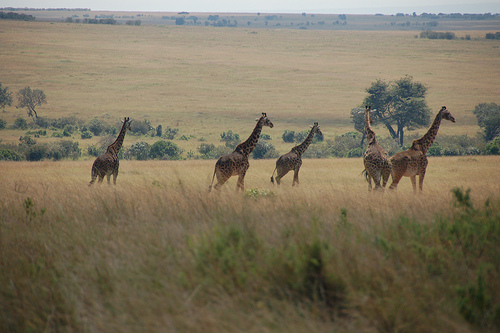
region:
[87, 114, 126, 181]
a tall giraffee wandering the plain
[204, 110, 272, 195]
a tall giraffee wandering the plain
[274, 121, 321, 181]
a tall giraffee wandering the plain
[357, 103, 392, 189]
a tall giraffee wandering the plain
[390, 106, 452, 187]
a tall giraffee wandering the plain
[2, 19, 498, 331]
a grassy plain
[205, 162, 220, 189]
a tail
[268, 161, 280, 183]
a giraffe tail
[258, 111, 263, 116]
a giraffe horn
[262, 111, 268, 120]
a giraffe horn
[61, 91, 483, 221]
giraffes out in a field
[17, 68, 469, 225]
many giraffes out in a field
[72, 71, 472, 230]
several giraffes out in a field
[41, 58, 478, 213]
multiple giraffes out in a field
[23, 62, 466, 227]
group of giraffes out in a field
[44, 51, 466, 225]
large set of giraffes out in a field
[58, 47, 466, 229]
big group of giraffes out in a field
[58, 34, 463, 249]
giraffes together in a field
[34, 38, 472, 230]
several giraffes together in a field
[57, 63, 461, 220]
multiple giraffes together in a field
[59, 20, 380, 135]
the field is wide green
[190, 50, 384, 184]
the field is wide green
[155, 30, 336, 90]
the field is wide green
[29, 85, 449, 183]
there are 5 zebras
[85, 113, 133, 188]
Last giraffe over on the left.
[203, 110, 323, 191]
Middle two giraffes.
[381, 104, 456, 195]
First giraffe to the right.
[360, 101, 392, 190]
Second giraffe to the right.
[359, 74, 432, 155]
Tree in front of two giraffes on the right side.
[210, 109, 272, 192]
The fourth giraffe from the right.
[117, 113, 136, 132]
The head of a left most giraffe.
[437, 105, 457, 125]
Head of a giraffe on the right.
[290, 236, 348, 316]
Dark tuft of grass up by the camera.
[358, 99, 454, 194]
First two giraffes on the right.